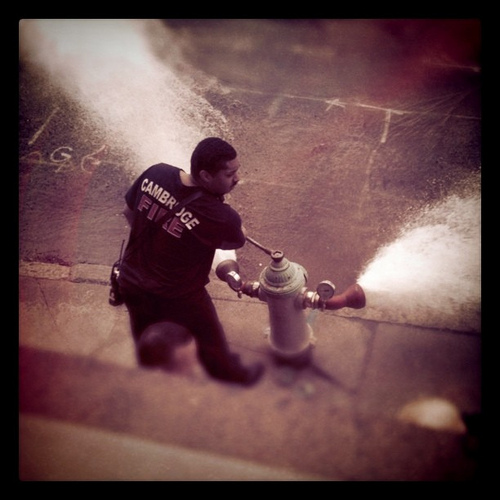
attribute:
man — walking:
[95, 136, 284, 418]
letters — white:
[134, 172, 208, 242]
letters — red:
[129, 193, 189, 245]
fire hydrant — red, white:
[216, 235, 377, 373]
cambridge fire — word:
[133, 174, 200, 237]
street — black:
[276, 21, 499, 254]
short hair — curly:
[178, 127, 239, 182]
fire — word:
[133, 192, 185, 242]